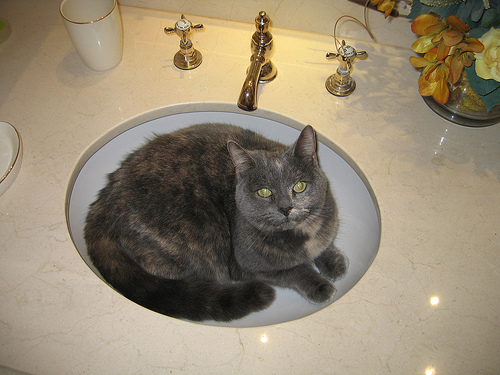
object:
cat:
[85, 120, 351, 322]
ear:
[290, 124, 319, 163]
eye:
[255, 187, 272, 198]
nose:
[277, 204, 294, 217]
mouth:
[269, 218, 308, 225]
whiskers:
[296, 208, 342, 244]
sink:
[63, 99, 384, 331]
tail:
[84, 225, 273, 323]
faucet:
[237, 9, 280, 112]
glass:
[58, 0, 126, 75]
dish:
[0, 118, 23, 190]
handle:
[163, 12, 206, 71]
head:
[226, 125, 329, 230]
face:
[236, 171, 327, 228]